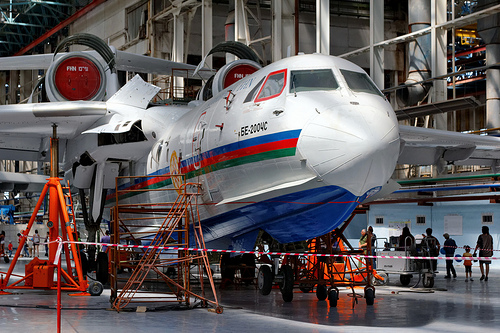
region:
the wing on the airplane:
[418, 122, 489, 162]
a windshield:
[289, 72, 335, 87]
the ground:
[242, 312, 281, 329]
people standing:
[415, 225, 460, 250]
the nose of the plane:
[324, 102, 401, 164]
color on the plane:
[231, 137, 279, 162]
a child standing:
[459, 244, 479, 274]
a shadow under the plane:
[349, 299, 416, 321]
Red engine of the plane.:
[40, 35, 115, 105]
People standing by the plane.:
[427, 221, 498, 271]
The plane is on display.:
[125, 64, 430, 276]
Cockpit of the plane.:
[263, 59, 385, 93]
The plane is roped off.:
[68, 233, 477, 273]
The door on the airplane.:
[166, 96, 221, 175]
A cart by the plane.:
[378, 239, 435, 279]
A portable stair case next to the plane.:
[136, 164, 226, 322]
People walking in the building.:
[16, 225, 59, 259]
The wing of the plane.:
[399, 102, 499, 162]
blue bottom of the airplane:
[134, 177, 362, 282]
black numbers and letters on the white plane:
[232, 117, 273, 137]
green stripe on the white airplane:
[102, 148, 302, 213]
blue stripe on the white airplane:
[106, 127, 302, 193]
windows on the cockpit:
[244, 71, 376, 93]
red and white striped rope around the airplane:
[60, 245, 498, 260]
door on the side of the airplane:
[182, 104, 216, 206]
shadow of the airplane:
[200, 257, 497, 332]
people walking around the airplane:
[365, 210, 495, 285]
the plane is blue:
[277, 208, 306, 230]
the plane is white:
[318, 103, 350, 138]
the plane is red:
[231, 150, 246, 157]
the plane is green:
[261, 150, 273, 162]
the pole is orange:
[46, 193, 59, 217]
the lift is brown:
[151, 200, 186, 224]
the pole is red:
[54, 294, 64, 320]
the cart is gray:
[389, 260, 405, 273]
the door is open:
[92, 123, 128, 147]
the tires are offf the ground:
[253, 259, 297, 304]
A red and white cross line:
[58, 235, 375, 263]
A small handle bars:
[215, 86, 237, 108]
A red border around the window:
[250, 64, 295, 107]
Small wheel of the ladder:
[211, 303, 231, 315]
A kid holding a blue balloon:
[451, 242, 475, 284]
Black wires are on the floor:
[81, 300, 224, 317]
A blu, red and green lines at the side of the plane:
[233, 130, 313, 164]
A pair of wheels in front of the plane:
[246, 257, 306, 295]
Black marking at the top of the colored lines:
[237, 115, 274, 146]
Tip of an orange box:
[23, 279, 41, 291]